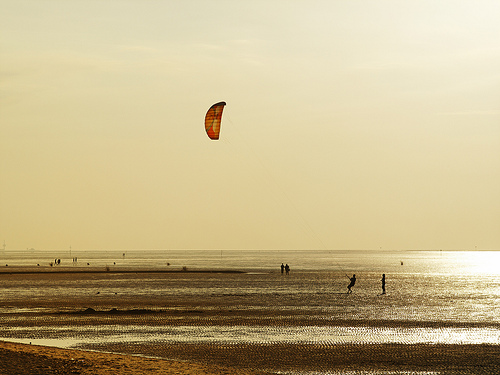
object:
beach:
[0, 264, 499, 374]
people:
[55, 258, 58, 264]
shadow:
[0, 348, 92, 375]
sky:
[0, 0, 500, 256]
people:
[347, 274, 357, 295]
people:
[380, 273, 386, 294]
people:
[74, 257, 77, 263]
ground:
[263, 337, 299, 375]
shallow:
[0, 260, 500, 351]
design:
[204, 100, 227, 140]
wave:
[21, 316, 496, 328]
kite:
[203, 101, 227, 141]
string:
[48, 121, 155, 279]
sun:
[416, 249, 498, 278]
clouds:
[0, 0, 497, 252]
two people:
[280, 262, 290, 275]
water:
[0, 248, 497, 348]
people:
[280, 262, 284, 276]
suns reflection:
[408, 244, 499, 289]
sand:
[0, 339, 249, 375]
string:
[222, 112, 347, 276]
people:
[284, 263, 290, 275]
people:
[72, 257, 75, 262]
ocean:
[0, 247, 500, 343]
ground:
[0, 330, 153, 375]